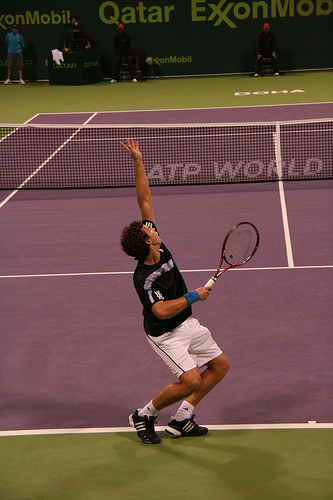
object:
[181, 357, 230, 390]
knees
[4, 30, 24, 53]
shirt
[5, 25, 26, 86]
man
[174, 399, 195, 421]
sock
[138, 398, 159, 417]
sock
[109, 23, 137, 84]
man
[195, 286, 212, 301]
hand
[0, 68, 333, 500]
floor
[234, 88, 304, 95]
sign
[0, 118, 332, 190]
net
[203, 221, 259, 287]
racket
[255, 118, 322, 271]
line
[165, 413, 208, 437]
shoe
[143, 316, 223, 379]
shorts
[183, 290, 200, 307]
sweatband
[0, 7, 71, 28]
lettering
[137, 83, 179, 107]
light green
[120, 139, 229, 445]
man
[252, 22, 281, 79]
person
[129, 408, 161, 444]
foot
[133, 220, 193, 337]
shirt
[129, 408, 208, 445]
tennis shoes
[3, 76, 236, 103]
sideline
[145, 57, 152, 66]
ball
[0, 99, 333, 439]
court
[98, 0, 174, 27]
lettering